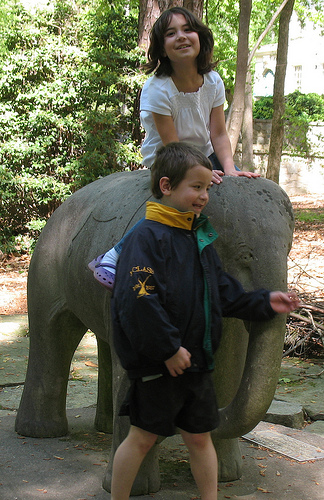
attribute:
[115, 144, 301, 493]
child — standing, little, young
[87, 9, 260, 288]
girl — sitting, little, smiling, young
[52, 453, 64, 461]
leaf — brown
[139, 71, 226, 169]
shirt — white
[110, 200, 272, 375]
jacket — blue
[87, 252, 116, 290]
shoe — purple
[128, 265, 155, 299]
logo — yellow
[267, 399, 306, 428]
stone — large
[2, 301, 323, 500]
floor — gray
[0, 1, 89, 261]
tree — green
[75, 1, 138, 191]
tree — green